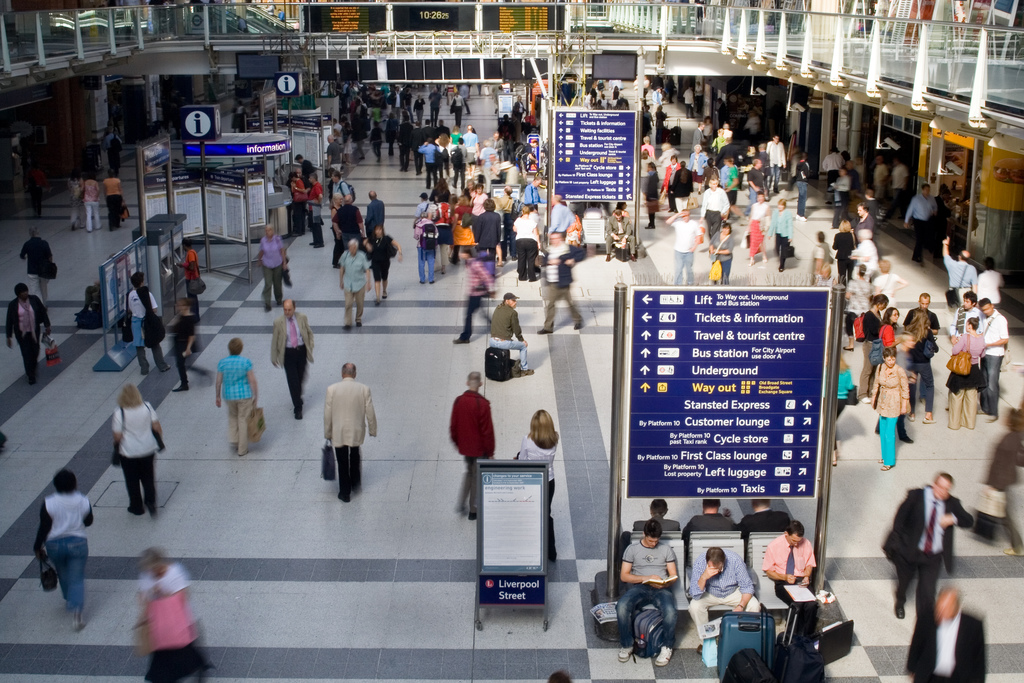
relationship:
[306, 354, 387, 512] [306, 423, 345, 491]
man holding bag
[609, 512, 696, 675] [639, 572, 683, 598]
man holding book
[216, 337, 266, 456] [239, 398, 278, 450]
lady carrying bag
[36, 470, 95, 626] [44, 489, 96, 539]
woman in shirt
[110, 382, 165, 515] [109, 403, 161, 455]
woman wearing blouse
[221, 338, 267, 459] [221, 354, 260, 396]
lady wearing shirt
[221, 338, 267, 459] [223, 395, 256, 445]
lady wearing pants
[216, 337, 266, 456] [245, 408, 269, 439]
lady carrying bag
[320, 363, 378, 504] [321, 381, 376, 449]
man in coat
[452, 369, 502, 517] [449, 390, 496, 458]
man wearing coat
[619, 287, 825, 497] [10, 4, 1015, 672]
sign in station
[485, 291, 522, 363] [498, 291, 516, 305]
man wearing hat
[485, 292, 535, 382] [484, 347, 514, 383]
man sitting on bag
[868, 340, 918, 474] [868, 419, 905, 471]
woman wearing pants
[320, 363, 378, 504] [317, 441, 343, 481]
man carrying a bag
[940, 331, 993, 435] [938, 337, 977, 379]
woman carrying a purse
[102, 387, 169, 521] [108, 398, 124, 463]
woman carrying a purse